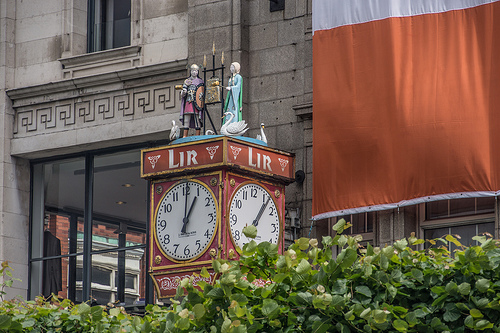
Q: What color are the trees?
A: Green.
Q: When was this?
A: Daytime.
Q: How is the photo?
A: Clear.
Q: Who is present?
A: Nobody.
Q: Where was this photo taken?
A: On the street.